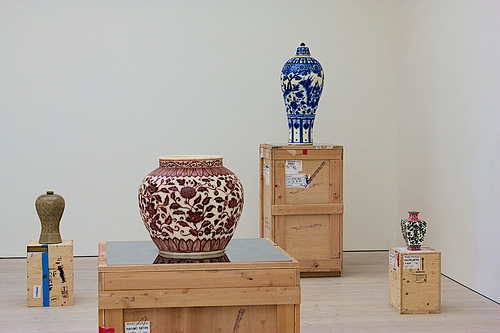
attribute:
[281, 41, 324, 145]
vase — ming, white, ceramic, blue, tall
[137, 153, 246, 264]
vase — ginger, ceramic, rose, purple, white, red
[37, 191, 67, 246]
vase — stoneware, small, green, brown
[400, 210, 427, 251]
vase — smaller, small, multi-colored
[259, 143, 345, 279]
crate — raw wood, vertical, tall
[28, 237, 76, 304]
crate — wooden, small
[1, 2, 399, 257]
wall — painted, white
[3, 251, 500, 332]
floor — clean, wood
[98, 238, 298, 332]
crate — tan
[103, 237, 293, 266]
surface — slick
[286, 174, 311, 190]
sticker — white